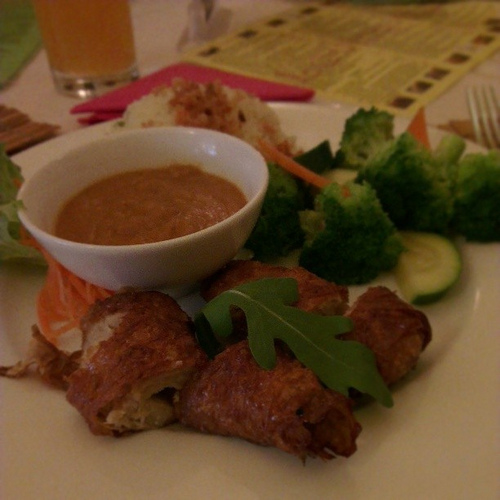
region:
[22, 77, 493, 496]
Round white plate with food on it.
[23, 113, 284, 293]
Small white bowl with dip in it.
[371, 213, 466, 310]
A slice of cucumber on the plate.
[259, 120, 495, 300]
Vegetables on the plate.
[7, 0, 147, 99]
A glass on the table behind the plate.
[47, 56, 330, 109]
Pink napkin on the table.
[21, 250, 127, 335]
Shredded carrots on the plate.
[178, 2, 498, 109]
Yellow menu on the table.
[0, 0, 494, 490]
No people shown in the picture.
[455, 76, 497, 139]
Fork on the table next to the plate.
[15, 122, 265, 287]
a bowl of dipping sauce on a plate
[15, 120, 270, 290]
the bowl is white on the plate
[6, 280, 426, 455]
fried rolled dough is on the plate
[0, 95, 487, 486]
the white dish has food on it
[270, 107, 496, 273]
green broccoli heads are on the plate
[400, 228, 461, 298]
a piece of cucumber is in the vegetables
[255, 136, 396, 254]
a slice of carrot is mixed with the broccoli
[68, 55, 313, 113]
a red folded napkin is on the table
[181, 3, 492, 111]
a menu is lying on the table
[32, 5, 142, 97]
a glass with a beverage is on the table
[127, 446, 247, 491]
this is a plate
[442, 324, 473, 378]
the plate is white in color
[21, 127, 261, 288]
this is a bowl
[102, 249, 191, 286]
the bowl is white in color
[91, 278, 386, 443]
this is some meat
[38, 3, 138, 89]
this is a glass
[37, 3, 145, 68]
the glass has some juice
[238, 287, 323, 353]
this is a leaf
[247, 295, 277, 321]
the leaf is green in color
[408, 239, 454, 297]
this is sliced lemon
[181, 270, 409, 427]
leaf is dark green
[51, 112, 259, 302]
Red sauce in white bowl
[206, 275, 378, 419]
Green leaf laying over top of food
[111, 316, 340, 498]
Brown flaky food underneath leaf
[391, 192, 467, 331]
Green vegetable near broccoli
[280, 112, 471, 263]
Broccoli, zucchini and carrots on plate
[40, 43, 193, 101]
Orange drink in glass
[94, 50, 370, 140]
Pink napkin folded on table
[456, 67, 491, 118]
Silver fork to the right of the dish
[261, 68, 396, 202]
Food on white plate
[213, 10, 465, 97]
Yellow piece of paper on table